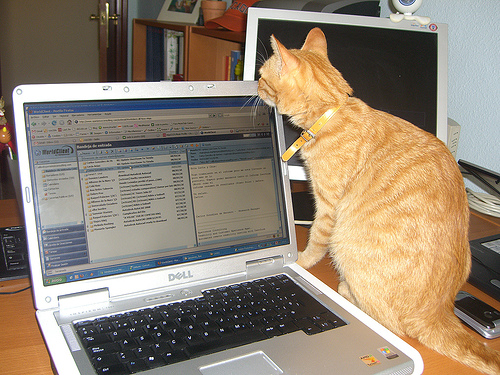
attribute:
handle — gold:
[91, 10, 120, 54]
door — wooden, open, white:
[90, 4, 117, 85]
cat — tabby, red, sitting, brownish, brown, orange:
[243, 45, 450, 307]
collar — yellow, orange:
[276, 103, 333, 161]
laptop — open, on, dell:
[36, 95, 402, 375]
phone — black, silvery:
[447, 289, 500, 347]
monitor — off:
[233, 13, 439, 184]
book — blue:
[226, 49, 252, 80]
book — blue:
[143, 25, 162, 74]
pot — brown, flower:
[201, 1, 236, 34]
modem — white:
[428, 115, 468, 165]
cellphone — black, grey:
[450, 281, 498, 335]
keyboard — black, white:
[84, 266, 300, 373]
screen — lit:
[34, 90, 265, 245]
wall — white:
[435, 23, 499, 110]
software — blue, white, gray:
[47, 115, 280, 256]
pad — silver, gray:
[207, 349, 272, 373]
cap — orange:
[212, 3, 265, 32]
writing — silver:
[169, 265, 191, 289]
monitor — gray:
[23, 92, 274, 264]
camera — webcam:
[390, 2, 423, 19]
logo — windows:
[380, 338, 396, 359]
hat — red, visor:
[216, 7, 259, 35]